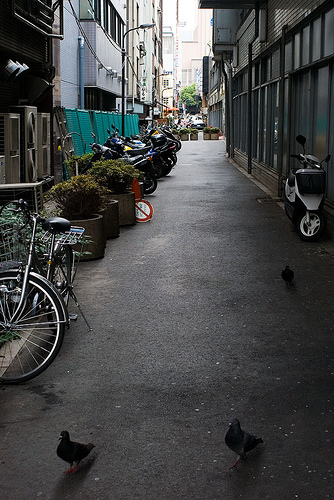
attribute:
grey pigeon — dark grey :
[37, 429, 104, 474]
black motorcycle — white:
[275, 133, 330, 244]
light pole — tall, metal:
[114, 14, 155, 135]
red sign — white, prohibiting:
[132, 197, 157, 224]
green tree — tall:
[174, 78, 210, 121]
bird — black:
[269, 260, 299, 290]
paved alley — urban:
[169, 128, 270, 412]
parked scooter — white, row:
[273, 134, 328, 246]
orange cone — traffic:
[123, 169, 149, 205]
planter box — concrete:
[211, 125, 222, 139]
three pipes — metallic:
[5, 58, 39, 83]